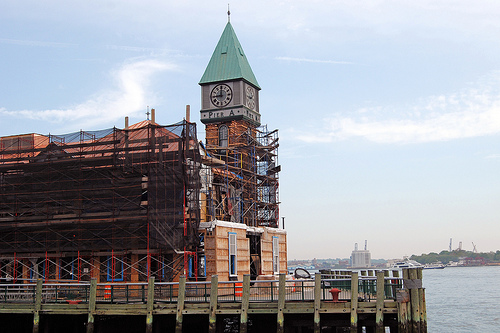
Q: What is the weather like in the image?
A: It is clear.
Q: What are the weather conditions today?
A: It is clear.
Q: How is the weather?
A: It is clear.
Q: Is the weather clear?
A: Yes, it is clear.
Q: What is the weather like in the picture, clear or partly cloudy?
A: It is clear.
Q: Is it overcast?
A: No, it is clear.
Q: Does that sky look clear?
A: Yes, the sky is clear.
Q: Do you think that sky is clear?
A: Yes, the sky is clear.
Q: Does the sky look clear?
A: Yes, the sky is clear.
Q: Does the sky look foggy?
A: No, the sky is clear.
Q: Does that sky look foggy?
A: No, the sky is clear.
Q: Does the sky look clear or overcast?
A: The sky is clear.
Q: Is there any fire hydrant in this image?
A: Yes, there is a fire hydrant.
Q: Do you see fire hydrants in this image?
A: Yes, there is a fire hydrant.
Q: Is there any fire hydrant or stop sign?
A: Yes, there is a fire hydrant.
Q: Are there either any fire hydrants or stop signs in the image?
A: Yes, there is a fire hydrant.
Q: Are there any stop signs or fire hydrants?
A: Yes, there is a fire hydrant.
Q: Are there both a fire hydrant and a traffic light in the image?
A: No, there is a fire hydrant but no traffic lights.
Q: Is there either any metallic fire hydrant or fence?
A: Yes, there is a metal fire hydrant.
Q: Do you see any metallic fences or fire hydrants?
A: Yes, there is a metal fire hydrant.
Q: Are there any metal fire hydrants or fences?
A: Yes, there is a metal fire hydrant.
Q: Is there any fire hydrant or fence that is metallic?
A: Yes, the fire hydrant is metallic.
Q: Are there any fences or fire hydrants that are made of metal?
A: Yes, the fire hydrant is made of metal.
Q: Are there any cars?
A: No, there are no cars.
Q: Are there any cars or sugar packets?
A: No, there are no cars or sugar packets.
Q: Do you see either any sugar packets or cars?
A: No, there are no cars or sugar packets.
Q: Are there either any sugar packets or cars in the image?
A: No, there are no cars or sugar packets.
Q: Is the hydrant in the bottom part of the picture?
A: Yes, the hydrant is in the bottom of the image.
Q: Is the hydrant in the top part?
A: No, the hydrant is in the bottom of the image.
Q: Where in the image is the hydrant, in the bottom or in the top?
A: The hydrant is in the bottom of the image.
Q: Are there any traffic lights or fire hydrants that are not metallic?
A: No, there is a fire hydrant but it is metallic.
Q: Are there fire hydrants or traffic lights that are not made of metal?
A: No, there is a fire hydrant but it is made of metal.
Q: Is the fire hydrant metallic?
A: Yes, the fire hydrant is metallic.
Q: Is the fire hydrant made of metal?
A: Yes, the fire hydrant is made of metal.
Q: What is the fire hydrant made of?
A: The hydrant is made of metal.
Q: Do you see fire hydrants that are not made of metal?
A: No, there is a fire hydrant but it is made of metal.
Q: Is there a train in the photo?
A: No, there are no trains.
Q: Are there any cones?
A: No, there are no cones.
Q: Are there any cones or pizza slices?
A: No, there are no cones or pizza slices.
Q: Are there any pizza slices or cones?
A: No, there are no cones or pizza slices.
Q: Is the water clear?
A: Yes, the water is clear.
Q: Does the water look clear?
A: Yes, the water is clear.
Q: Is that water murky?
A: No, the water is clear.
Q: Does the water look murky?
A: No, the water is clear.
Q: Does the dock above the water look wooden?
A: Yes, the dock is wooden.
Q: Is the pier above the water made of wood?
A: Yes, the pier is made of wood.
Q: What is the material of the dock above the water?
A: The dock is made of wood.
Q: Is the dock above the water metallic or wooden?
A: The pier is wooden.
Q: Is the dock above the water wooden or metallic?
A: The pier is wooden.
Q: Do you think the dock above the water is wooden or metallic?
A: The pier is wooden.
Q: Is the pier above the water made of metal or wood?
A: The dock is made of wood.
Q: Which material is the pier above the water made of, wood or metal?
A: The dock is made of wood.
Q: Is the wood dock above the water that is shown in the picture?
A: Yes, the pier is above the water.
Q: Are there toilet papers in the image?
A: No, there are no toilet papers.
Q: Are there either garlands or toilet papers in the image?
A: No, there are no toilet papers or garlands.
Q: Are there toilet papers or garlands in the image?
A: No, there are no toilet papers or garlands.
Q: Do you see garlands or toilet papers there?
A: No, there are no toilet papers or garlands.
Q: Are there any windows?
A: Yes, there is a window.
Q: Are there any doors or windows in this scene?
A: Yes, there is a window.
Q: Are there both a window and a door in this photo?
A: No, there is a window but no doors.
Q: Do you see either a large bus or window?
A: Yes, there is a large window.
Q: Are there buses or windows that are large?
A: Yes, the window is large.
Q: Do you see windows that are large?
A: Yes, there is a large window.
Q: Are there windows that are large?
A: Yes, there is a large window.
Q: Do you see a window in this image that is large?
A: Yes, there is a window that is large.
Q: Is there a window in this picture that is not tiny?
A: Yes, there is a large window.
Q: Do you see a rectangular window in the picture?
A: Yes, there is a rectangular window.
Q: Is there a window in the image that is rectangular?
A: Yes, there is a window that is rectangular.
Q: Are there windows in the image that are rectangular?
A: Yes, there is a window that is rectangular.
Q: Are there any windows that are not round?
A: Yes, there is a rectangular window.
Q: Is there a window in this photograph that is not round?
A: Yes, there is a rectangular window.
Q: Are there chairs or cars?
A: No, there are no cars or chairs.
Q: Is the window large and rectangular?
A: Yes, the window is large and rectangular.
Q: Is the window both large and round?
A: No, the window is large but rectangular.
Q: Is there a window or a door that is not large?
A: No, there is a window but it is large.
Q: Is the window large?
A: Yes, the window is large.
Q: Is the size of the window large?
A: Yes, the window is large.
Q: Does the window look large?
A: Yes, the window is large.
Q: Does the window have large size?
A: Yes, the window is large.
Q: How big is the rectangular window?
A: The window is large.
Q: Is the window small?
A: No, the window is large.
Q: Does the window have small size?
A: No, the window is large.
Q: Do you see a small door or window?
A: No, there is a window but it is large.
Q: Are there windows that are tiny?
A: No, there is a window but it is large.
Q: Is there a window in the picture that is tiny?
A: No, there is a window but it is large.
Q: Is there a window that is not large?
A: No, there is a window but it is large.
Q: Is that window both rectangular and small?
A: No, the window is rectangular but large.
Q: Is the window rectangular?
A: Yes, the window is rectangular.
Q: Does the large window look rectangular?
A: Yes, the window is rectangular.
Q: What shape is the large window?
A: The window is rectangular.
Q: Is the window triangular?
A: No, the window is rectangular.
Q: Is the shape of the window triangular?
A: No, the window is rectangular.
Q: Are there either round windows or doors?
A: No, there is a window but it is rectangular.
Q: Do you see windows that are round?
A: No, there is a window but it is rectangular.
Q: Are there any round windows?
A: No, there is a window but it is rectangular.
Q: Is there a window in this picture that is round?
A: No, there is a window but it is rectangular.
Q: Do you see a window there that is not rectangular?
A: No, there is a window but it is rectangular.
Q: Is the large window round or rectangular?
A: The window is rectangular.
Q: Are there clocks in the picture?
A: Yes, there is a clock.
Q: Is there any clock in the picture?
A: Yes, there is a clock.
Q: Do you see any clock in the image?
A: Yes, there is a clock.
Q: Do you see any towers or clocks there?
A: Yes, there is a clock.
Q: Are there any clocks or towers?
A: Yes, there is a clock.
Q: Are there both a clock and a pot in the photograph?
A: No, there is a clock but no pots.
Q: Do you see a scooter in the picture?
A: No, there are no scooters.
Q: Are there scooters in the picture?
A: No, there are no scooters.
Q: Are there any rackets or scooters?
A: No, there are no scooters or rackets.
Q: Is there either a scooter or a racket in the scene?
A: No, there are no scooters or rackets.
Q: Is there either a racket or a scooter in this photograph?
A: No, there are no scooters or rackets.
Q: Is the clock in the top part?
A: Yes, the clock is in the top of the image.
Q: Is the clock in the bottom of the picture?
A: No, the clock is in the top of the image.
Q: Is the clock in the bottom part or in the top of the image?
A: The clock is in the top of the image.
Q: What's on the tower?
A: The clock is on the tower.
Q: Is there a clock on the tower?
A: Yes, there is a clock on the tower.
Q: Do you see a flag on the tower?
A: No, there is a clock on the tower.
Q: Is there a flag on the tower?
A: No, there is a clock on the tower.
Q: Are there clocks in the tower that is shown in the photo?
A: Yes, there is a clock in the tower.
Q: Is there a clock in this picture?
A: Yes, there is a clock.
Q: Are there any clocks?
A: Yes, there is a clock.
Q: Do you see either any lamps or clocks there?
A: Yes, there is a clock.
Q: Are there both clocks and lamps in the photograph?
A: No, there is a clock but no lamps.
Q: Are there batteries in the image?
A: No, there are no batteries.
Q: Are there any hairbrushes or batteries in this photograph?
A: No, there are no batteries or hairbrushes.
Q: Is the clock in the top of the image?
A: Yes, the clock is in the top of the image.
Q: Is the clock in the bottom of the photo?
A: No, the clock is in the top of the image.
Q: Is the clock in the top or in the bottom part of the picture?
A: The clock is in the top of the image.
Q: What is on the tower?
A: The clock is on the tower.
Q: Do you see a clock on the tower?
A: Yes, there is a clock on the tower.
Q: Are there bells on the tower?
A: No, there is a clock on the tower.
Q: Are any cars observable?
A: No, there are no cars.